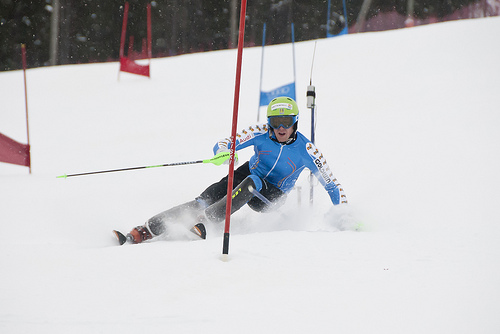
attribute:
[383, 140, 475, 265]
snow — smooth, white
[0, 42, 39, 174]
flag — red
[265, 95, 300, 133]
helmet — green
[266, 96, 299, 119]
helmet — green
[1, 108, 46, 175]
sign — red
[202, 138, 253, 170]
pole — green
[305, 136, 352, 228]
sleeve — long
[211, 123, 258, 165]
sleeve — long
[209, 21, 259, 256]
pole — red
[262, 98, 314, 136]
helmet — lime-green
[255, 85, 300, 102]
flag — blue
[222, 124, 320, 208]
jacket — blue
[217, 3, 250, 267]
pole — green, gray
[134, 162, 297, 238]
pants — black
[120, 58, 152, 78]
sign — red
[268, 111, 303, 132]
goggles — blue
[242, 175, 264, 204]
band — blue